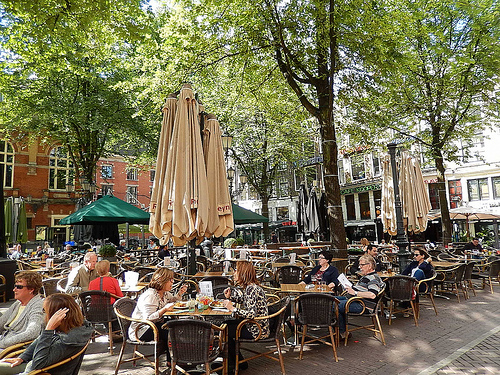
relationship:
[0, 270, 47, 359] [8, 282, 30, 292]
man in sunglasses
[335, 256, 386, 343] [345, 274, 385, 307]
man in shirt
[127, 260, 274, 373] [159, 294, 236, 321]
women in table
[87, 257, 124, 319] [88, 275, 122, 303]
person in shirt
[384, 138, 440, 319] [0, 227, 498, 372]
metal pole in dining area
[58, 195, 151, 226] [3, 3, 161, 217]
canopy under tree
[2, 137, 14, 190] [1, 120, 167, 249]
window on building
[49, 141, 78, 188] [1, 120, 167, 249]
window on building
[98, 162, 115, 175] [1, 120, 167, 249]
window on building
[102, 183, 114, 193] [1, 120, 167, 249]
window on building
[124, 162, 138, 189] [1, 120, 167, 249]
window on building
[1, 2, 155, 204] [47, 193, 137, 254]
tree in caffee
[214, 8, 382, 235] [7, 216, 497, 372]
tree in cafe area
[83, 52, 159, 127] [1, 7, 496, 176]
leaves in trees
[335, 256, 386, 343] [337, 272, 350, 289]
man looking at menu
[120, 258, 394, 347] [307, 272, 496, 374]
chairs looking at patio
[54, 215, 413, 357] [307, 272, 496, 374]
table looking at patio